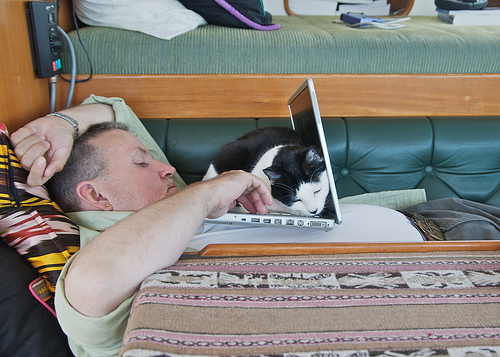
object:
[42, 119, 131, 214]
hair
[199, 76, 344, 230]
laptop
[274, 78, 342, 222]
screen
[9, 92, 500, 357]
guy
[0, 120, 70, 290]
pillow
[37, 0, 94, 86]
wire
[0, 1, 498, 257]
wood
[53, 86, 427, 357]
green shirt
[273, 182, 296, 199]
whiskers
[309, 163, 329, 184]
whiskers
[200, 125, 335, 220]
cat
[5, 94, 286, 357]
dude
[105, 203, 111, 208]
earring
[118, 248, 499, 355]
rug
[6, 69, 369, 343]
work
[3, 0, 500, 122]
bed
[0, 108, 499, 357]
sofa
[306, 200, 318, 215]
nose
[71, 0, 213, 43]
pillow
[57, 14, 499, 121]
upper bed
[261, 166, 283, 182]
ear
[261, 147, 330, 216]
cat's face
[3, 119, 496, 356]
couch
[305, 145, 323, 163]
ear